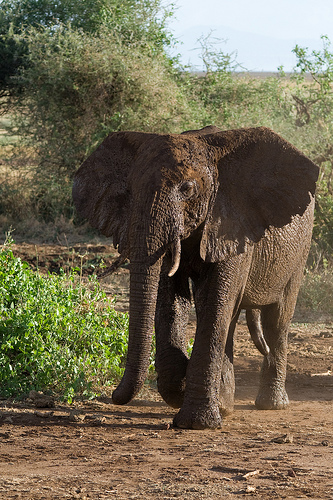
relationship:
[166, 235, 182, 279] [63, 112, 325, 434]
tusk of elephant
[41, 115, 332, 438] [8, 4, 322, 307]
elephant in forest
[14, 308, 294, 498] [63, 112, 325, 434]
dirt near elephant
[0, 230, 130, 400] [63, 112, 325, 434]
plant near elephant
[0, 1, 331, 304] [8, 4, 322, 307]
forest in forest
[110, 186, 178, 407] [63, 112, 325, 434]
trunk of elephant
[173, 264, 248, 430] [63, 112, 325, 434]
leg of elephant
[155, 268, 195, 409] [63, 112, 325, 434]
leg of elephant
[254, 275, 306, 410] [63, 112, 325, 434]
leg of elephant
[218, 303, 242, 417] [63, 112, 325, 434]
leg of elephant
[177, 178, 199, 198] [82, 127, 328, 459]
eye of elephant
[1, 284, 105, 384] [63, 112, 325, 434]
bush near elephant